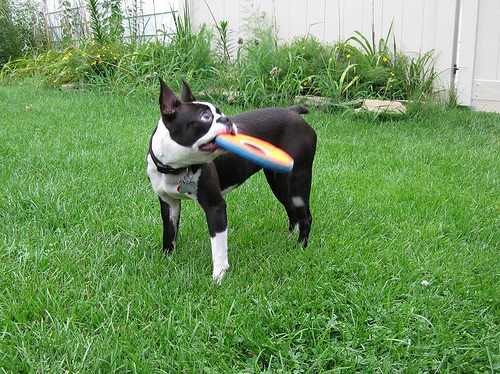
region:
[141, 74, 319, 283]
A black and white boston terrier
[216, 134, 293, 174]
A colored frisbee in a dogs mouth.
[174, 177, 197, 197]
Two dog tags hang from a dogs neck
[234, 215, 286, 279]
Grass between a dogs legs.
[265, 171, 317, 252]
Hind legs of a Boston Terrier.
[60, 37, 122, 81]
Yellow flowers and grass on the upper left.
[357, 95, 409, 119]
Flat rock on the end of a flower bed.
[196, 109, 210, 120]
Eye of a boston terrier dog.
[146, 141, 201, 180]
A black collar on a dogs neck.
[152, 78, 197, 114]
Two black ears on a boston terriers head.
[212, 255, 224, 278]
the dog is black and white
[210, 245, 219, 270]
the dog is black and white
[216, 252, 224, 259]
the dog is black and white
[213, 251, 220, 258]
the dog is black and white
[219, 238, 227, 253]
the dog is black and white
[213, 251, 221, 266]
the dog is black and white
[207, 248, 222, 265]
the dog is black and white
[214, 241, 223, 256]
the dog is black and white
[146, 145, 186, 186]
the dog is wearing a collar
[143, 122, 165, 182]
the collar is tight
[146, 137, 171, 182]
the collar is black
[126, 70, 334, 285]
the dog is small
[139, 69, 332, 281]
the dog is black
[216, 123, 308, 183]
the dog is carrying a frisbee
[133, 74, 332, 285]
the dog is white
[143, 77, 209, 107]
the dog has ears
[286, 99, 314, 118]
the dog has a very tiny tail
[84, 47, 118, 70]
the flowers are yellow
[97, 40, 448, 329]
this dog is a french bulldog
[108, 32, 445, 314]
this dog is a boston terrier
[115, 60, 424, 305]
this dog is black and white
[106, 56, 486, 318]
the dog has a frisbee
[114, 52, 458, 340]
the dog is looking at something off camera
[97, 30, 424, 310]
the dog has a bone shaped tag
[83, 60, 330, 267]
the frisbee is rainbow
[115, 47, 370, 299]
the dog has one white leg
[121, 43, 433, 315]
the dog is in a yard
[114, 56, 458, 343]
the dog is alert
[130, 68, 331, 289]
a dog on a green field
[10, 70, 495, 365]
a field cover with green grass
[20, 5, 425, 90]
plants growing in front of building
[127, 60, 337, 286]
dog is white and black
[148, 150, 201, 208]
chest of a dog is white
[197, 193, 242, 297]
left leg of a dog is white and black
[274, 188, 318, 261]
back legs of dog are black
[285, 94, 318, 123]
tail of dog is short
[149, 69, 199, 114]
pointy ears of dog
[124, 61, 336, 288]
dog holding a Frisbee in his mouth